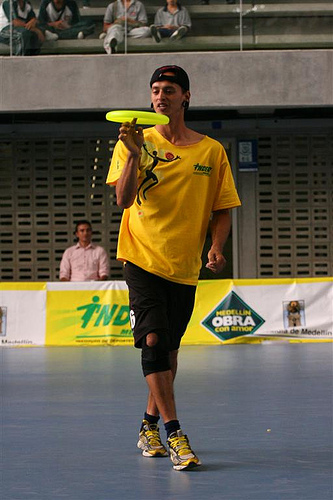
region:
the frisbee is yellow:
[102, 107, 171, 127]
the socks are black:
[141, 408, 182, 435]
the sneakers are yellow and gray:
[136, 415, 201, 471]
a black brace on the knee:
[137, 319, 173, 377]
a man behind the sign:
[55, 215, 114, 344]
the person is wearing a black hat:
[146, 62, 192, 119]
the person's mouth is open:
[144, 64, 193, 124]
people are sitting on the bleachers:
[1, 0, 194, 56]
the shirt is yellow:
[104, 126, 240, 285]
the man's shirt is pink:
[59, 219, 113, 285]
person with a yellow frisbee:
[104, 63, 225, 458]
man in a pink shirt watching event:
[49, 216, 115, 281]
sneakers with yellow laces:
[118, 420, 200, 470]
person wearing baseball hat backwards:
[111, 64, 204, 152]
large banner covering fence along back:
[17, 273, 322, 345]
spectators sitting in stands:
[5, 0, 193, 63]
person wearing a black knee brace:
[134, 317, 172, 382]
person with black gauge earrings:
[140, 99, 197, 113]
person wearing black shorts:
[117, 253, 205, 349]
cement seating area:
[218, 1, 324, 46]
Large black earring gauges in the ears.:
[150, 99, 188, 107]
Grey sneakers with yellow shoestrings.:
[132, 421, 200, 471]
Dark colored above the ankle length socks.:
[137, 414, 181, 435]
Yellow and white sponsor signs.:
[1, 277, 331, 343]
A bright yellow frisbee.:
[104, 110, 172, 123]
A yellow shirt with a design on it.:
[107, 128, 241, 286]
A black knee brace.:
[135, 333, 169, 374]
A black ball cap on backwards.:
[146, 64, 195, 84]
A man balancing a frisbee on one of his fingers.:
[106, 62, 237, 468]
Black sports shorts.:
[124, 262, 195, 349]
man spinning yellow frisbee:
[100, 98, 185, 150]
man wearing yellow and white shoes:
[168, 429, 194, 471]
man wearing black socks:
[156, 413, 187, 448]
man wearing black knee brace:
[138, 327, 181, 382]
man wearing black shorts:
[124, 293, 193, 327]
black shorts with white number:
[121, 307, 144, 332]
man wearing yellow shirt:
[104, 134, 219, 263]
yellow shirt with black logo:
[141, 142, 168, 201]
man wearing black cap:
[145, 60, 212, 98]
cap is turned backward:
[145, 62, 200, 94]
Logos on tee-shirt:
[137, 137, 218, 210]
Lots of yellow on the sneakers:
[122, 421, 209, 473]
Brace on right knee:
[126, 317, 180, 382]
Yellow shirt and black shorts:
[79, 113, 268, 353]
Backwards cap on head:
[134, 52, 203, 95]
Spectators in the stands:
[2, 1, 221, 65]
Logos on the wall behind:
[3, 276, 332, 347]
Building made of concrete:
[2, 37, 330, 120]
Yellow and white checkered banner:
[2, 277, 331, 358]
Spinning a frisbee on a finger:
[82, 101, 180, 217]